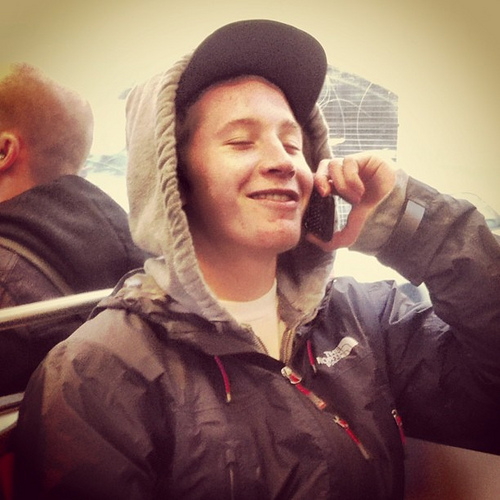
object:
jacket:
[56, 275, 456, 473]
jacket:
[64, 287, 453, 492]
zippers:
[277, 351, 399, 465]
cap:
[184, 14, 329, 104]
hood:
[103, 60, 344, 304]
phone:
[295, 180, 344, 253]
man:
[8, 71, 119, 338]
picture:
[2, 3, 488, 497]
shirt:
[230, 291, 313, 349]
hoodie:
[122, 57, 336, 319]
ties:
[208, 338, 330, 395]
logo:
[317, 330, 358, 365]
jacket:
[57, 268, 374, 482]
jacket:
[81, 270, 377, 460]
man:
[188, 80, 325, 260]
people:
[18, 62, 358, 402]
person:
[166, 90, 336, 390]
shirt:
[208, 275, 314, 387]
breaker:
[18, 259, 424, 487]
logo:
[322, 330, 360, 368]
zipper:
[274, 360, 387, 472]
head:
[0, 62, 96, 187]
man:
[100, 16, 403, 466]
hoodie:
[116, 44, 350, 305]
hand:
[311, 146, 409, 254]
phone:
[295, 171, 341, 245]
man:
[127, 32, 405, 410]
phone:
[292, 178, 342, 239]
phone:
[306, 183, 341, 244]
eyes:
[217, 128, 304, 156]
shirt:
[200, 287, 294, 366]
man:
[117, 21, 386, 486]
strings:
[208, 339, 322, 397]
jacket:
[56, 279, 409, 457]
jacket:
[67, 280, 412, 445]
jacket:
[43, 280, 423, 479]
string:
[203, 351, 240, 408]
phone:
[296, 193, 338, 245]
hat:
[147, 20, 336, 106]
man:
[130, 25, 390, 445]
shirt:
[217, 278, 306, 368]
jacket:
[62, 284, 382, 462]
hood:
[122, 65, 336, 316]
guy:
[0, 60, 130, 333]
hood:
[0, 169, 131, 282]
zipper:
[217, 443, 261, 495]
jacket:
[90, 324, 292, 442]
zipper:
[273, 358, 370, 452]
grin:
[242, 184, 307, 218]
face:
[175, 91, 329, 258]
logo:
[309, 328, 363, 376]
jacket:
[133, 328, 329, 434]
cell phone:
[307, 164, 348, 251]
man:
[10, 67, 105, 442]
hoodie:
[110, 69, 237, 354]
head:
[170, 61, 320, 254]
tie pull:
[199, 360, 240, 410]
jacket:
[115, 361, 252, 439]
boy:
[21, 19, 498, 494]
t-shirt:
[235, 290, 300, 362]